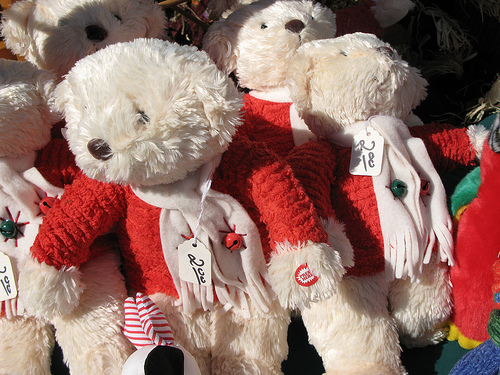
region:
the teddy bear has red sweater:
[76, 200, 342, 262]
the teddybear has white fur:
[96, 100, 221, 147]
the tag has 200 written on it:
[180, 236, 223, 287]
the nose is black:
[85, 140, 106, 156]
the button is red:
[225, 232, 241, 249]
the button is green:
[382, 175, 402, 190]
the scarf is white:
[143, 195, 269, 299]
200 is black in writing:
[186, 255, 208, 286]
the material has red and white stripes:
[125, 297, 180, 346]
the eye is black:
[130, 110, 152, 125]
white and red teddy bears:
[12, 4, 474, 361]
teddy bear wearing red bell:
[198, 213, 270, 263]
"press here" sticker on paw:
[283, 248, 335, 301]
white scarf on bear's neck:
[322, 105, 459, 275]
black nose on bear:
[60, 121, 137, 168]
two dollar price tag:
[170, 213, 234, 315]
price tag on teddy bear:
[296, 24, 444, 194]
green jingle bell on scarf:
[383, 167, 416, 217]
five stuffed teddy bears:
[2, 4, 437, 260]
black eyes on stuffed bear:
[74, 86, 156, 131]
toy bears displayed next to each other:
[15, 25, 465, 347]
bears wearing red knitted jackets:
[25, 141, 480, 306]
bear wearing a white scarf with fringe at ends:
[130, 150, 285, 325]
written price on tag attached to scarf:
[162, 195, 242, 305]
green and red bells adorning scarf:
[380, 175, 447, 210]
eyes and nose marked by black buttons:
[56, 91, 171, 161]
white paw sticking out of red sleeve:
[10, 230, 100, 327]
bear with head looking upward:
[281, 25, 441, 135]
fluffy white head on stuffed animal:
[40, 30, 252, 191]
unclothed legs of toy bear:
[295, 237, 470, 368]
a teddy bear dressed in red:
[20, 36, 345, 370]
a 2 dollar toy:
[22, 38, 342, 344]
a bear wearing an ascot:
[11, 38, 343, 327]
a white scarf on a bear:
[16, 39, 335, 370]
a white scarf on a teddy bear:
[13, 32, 341, 374]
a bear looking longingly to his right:
[16, 34, 337, 371]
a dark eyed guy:
[19, 38, 341, 371]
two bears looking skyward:
[233, 0, 434, 126]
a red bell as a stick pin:
[207, 217, 255, 264]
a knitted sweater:
[20, 123, 341, 310]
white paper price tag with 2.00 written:
[176, 237, 216, 288]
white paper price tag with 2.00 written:
[0, 249, 17, 301]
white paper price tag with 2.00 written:
[348, 122, 384, 173]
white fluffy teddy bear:
[37, 51, 334, 371]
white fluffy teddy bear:
[282, 30, 459, 372]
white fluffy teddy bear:
[0, 59, 128, 373]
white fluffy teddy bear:
[7, 1, 167, 72]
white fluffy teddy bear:
[207, 2, 341, 94]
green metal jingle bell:
[388, 179, 406, 196]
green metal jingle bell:
[2, 220, 18, 240]